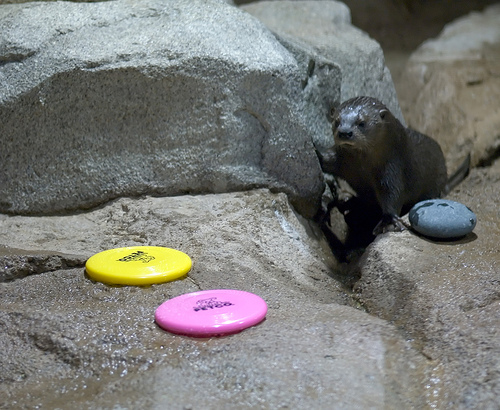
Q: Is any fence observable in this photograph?
A: No, there are no fences.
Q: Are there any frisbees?
A: Yes, there is a frisbee.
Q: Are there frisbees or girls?
A: Yes, there is a frisbee.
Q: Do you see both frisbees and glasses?
A: No, there is a frisbee but no glasses.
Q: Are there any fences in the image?
A: No, there are no fences.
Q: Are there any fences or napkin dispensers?
A: No, there are no fences or napkin dispensers.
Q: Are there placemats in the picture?
A: No, there are no placemats.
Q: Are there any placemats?
A: No, there are no placemats.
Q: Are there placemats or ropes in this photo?
A: No, there are no placemats or ropes.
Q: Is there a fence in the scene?
A: No, there are no fences.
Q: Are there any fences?
A: No, there are no fences.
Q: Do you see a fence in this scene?
A: No, there are no fences.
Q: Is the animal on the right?
A: Yes, the animal is on the right of the image.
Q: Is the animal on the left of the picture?
A: No, the animal is on the right of the image.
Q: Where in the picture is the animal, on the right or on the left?
A: The animal is on the right of the image.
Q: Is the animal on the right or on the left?
A: The animal is on the right of the image.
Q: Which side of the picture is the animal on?
A: The animal is on the right of the image.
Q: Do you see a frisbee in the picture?
A: Yes, there is a frisbee.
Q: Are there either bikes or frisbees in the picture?
A: Yes, there is a frisbee.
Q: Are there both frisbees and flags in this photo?
A: No, there is a frisbee but no flags.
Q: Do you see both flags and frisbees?
A: No, there is a frisbee but no flags.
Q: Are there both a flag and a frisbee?
A: No, there is a frisbee but no flags.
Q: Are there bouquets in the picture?
A: No, there are no bouquets.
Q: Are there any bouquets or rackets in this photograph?
A: No, there are no bouquets or rackets.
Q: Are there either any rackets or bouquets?
A: No, there are no bouquets or rackets.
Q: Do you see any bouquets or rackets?
A: No, there are no bouquets or rackets.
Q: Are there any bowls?
A: No, there are no bowls.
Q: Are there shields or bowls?
A: No, there are no bowls or shields.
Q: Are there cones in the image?
A: No, there are no cones.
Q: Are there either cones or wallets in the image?
A: No, there are no cones or wallets.